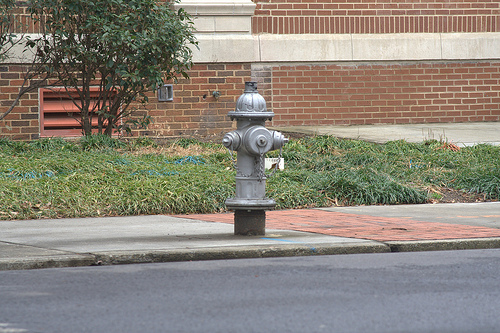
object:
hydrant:
[220, 80, 291, 236]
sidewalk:
[164, 221, 202, 237]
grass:
[84, 173, 122, 200]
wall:
[323, 84, 363, 114]